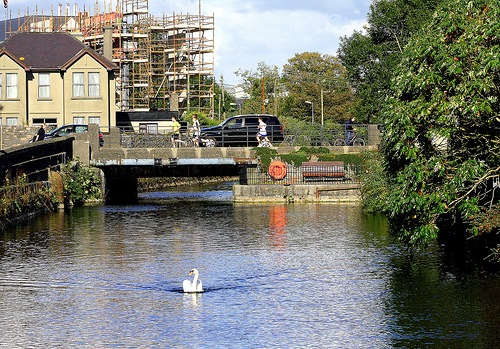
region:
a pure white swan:
[174, 267, 208, 299]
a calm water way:
[69, 192, 433, 333]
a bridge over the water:
[86, 125, 270, 209]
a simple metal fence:
[96, 125, 375, 157]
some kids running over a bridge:
[157, 113, 274, 148]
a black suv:
[188, 107, 294, 151]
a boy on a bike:
[326, 111, 368, 152]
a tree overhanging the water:
[363, 66, 484, 265]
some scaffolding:
[146, 6, 218, 125]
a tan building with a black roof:
[0, 25, 120, 139]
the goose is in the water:
[176, 265, 212, 295]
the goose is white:
[176, 261, 210, 298]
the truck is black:
[212, 110, 292, 155]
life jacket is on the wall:
[266, 157, 288, 181]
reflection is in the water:
[266, 205, 293, 225]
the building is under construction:
[121, 11, 216, 111]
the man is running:
[249, 111, 278, 146]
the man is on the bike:
[344, 116, 360, 144]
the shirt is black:
[31, 125, 48, 142]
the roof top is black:
[128, 109, 180, 121]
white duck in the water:
[176, 254, 229, 304]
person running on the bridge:
[246, 118, 276, 156]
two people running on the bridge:
[161, 117, 227, 148]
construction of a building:
[96, 18, 225, 104]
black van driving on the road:
[206, 115, 284, 150]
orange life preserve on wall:
[272, 158, 286, 188]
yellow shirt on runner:
[170, 119, 187, 136]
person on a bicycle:
[333, 116, 363, 157]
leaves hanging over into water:
[376, 158, 492, 278]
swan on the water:
[177, 258, 217, 293]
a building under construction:
[97, 0, 214, 122]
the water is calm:
[42, 269, 99, 323]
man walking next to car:
[200, 102, 287, 140]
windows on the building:
[2, 78, 77, 125]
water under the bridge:
[107, 158, 237, 219]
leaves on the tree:
[385, 86, 471, 233]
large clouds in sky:
[255, 20, 332, 51]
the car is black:
[207, 125, 238, 139]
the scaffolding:
[37, 7, 233, 114]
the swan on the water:
[142, 263, 220, 303]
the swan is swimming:
[175, 262, 214, 297]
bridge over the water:
[69, 118, 281, 213]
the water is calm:
[47, 198, 498, 347]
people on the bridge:
[174, 111, 278, 137]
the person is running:
[248, 119, 274, 140]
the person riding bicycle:
[317, 114, 367, 145]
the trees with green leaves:
[375, 16, 497, 207]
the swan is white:
[179, 270, 214, 299]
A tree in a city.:
[398, 12, 499, 234]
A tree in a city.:
[343, 13, 456, 130]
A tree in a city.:
[336, 25, 399, 80]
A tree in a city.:
[281, 50, 392, 126]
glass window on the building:
[86, 72, 96, 82]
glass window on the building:
[88, 82, 99, 93]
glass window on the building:
[37, 72, 47, 82]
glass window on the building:
[36, 85, 46, 97]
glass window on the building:
[3, 73, 13, 84]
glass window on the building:
[5, 86, 16, 96]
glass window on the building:
[86, 115, 97, 126]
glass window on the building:
[72, 115, 84, 123]